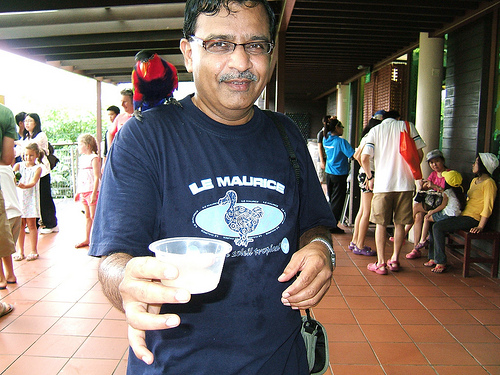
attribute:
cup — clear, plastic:
[147, 232, 232, 296]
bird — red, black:
[129, 53, 179, 115]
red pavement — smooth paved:
[0, 195, 499, 374]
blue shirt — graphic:
[86, 88, 335, 373]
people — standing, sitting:
[315, 89, 498, 288]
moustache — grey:
[217, 70, 259, 85]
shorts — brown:
[368, 187, 415, 228]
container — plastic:
[148, 235, 230, 297]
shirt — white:
[341, 103, 427, 203]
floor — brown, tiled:
[368, 285, 448, 342]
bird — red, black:
[126, 52, 180, 123]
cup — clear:
[142, 235, 246, 296]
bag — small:
[300, 306, 329, 373]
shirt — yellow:
[456, 171, 496, 225]